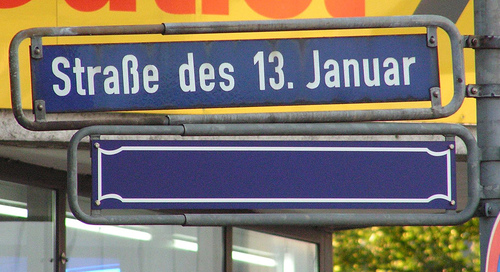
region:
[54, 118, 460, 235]
street sign is blue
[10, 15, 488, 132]
street sign is blue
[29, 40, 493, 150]
the text is white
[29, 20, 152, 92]
the text is white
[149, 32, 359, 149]
the text is white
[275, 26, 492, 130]
the text is white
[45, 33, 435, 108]
the text is white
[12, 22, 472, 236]
a road sign written in spanish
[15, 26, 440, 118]
blue road sign written in spanish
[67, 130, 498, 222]
blue road sign with nothing on it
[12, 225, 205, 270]
glass windows behind a road sign written in spanish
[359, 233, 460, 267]
green leaves behind a road sign written in spanish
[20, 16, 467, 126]
a road sign written in spanish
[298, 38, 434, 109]
white letters on sign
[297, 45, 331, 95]
the letter J on sign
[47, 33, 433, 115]
words on the sign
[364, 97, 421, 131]
gray metal of the sign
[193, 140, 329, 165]
white line on the sign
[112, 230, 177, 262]
window next to sign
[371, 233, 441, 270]
leaves in the background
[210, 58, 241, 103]
the letter "s" on sign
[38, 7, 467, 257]
two different signs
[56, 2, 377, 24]
orange and yellow sign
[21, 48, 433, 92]
this is a signpost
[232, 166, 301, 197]
the signpost is blue in color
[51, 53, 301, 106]
this is a writing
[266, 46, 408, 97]
the writing is in white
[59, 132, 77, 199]
this is the frame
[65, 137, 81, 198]
this is a metal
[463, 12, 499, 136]
this is a pole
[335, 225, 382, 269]
this is a tree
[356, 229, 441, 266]
the leaves are green in color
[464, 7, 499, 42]
the pole is metallic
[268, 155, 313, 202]
part of a board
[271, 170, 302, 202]
part of a board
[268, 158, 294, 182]
part of a board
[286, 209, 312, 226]
part of a metal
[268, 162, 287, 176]
part of a board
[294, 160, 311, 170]
part of a board